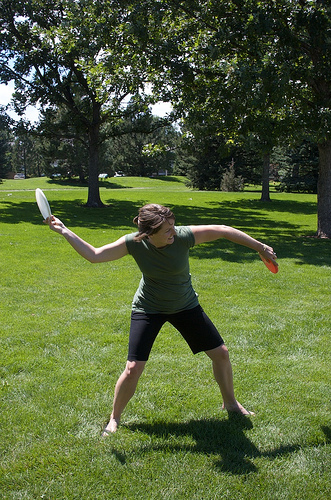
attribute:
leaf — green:
[16, 110, 26, 115]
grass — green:
[6, 259, 78, 483]